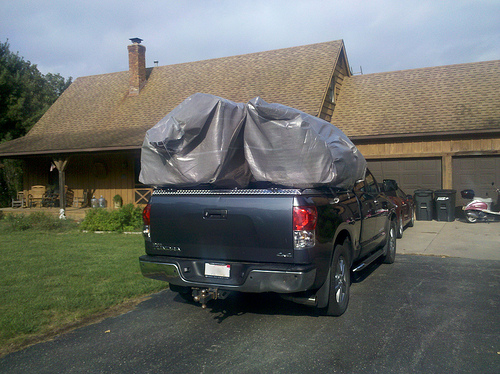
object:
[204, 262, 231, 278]
tag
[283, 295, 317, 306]
muffler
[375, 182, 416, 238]
car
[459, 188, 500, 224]
motorcycle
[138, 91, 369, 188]
covered object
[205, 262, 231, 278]
license plate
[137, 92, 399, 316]
blue truck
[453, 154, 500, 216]
door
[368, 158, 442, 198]
door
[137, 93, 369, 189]
cargo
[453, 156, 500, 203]
column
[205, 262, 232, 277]
license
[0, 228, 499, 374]
driveway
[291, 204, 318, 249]
brakelights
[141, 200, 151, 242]
brakelights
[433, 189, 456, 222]
cans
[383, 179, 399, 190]
mirror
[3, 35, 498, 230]
house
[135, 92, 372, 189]
tarp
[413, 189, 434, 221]
trash barrel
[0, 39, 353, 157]
roof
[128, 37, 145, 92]
chimney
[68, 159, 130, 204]
wood panel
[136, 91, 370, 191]
furniture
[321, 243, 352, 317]
tire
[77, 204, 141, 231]
bushes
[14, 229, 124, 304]
grass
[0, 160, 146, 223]
porch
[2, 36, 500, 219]
home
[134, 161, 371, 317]
pick up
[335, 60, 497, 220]
garage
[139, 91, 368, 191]
object